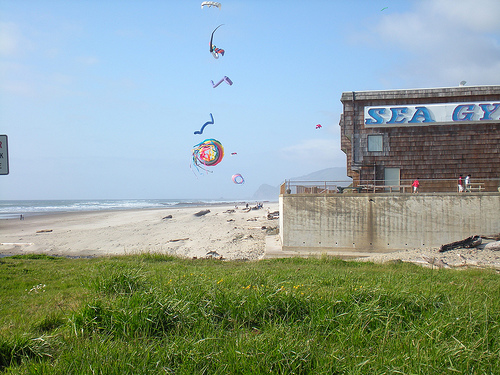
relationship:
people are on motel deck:
[407, 167, 482, 196] [283, 169, 500, 201]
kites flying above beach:
[183, 2, 331, 195] [7, 197, 283, 259]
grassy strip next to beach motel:
[1, 252, 500, 372] [259, 83, 500, 257]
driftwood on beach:
[192, 204, 217, 224] [7, 197, 283, 259]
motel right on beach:
[259, 83, 500, 257] [7, 197, 283, 259]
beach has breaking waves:
[7, 197, 283, 259] [3, 197, 168, 214]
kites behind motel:
[183, 2, 331, 195] [259, 83, 500, 257]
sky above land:
[3, 1, 494, 100] [2, 207, 497, 370]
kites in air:
[183, 2, 331, 195] [6, 5, 329, 186]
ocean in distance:
[4, 193, 265, 211] [3, 180, 337, 208]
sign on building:
[355, 99, 499, 133] [259, 83, 500, 257]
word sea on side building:
[364, 97, 443, 132] [259, 83, 500, 257]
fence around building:
[283, 169, 500, 201] [259, 83, 500, 257]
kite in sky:
[189, 135, 229, 174] [3, 1, 494, 100]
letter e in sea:
[384, 100, 411, 128] [364, 97, 443, 132]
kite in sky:
[189, 135, 229, 174] [203, 19, 234, 63]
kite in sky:
[206, 71, 235, 92] [3, 1, 494, 100]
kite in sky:
[198, 1, 225, 12] [3, 1, 494, 100]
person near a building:
[456, 170, 467, 192] [259, 83, 500, 257]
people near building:
[411, 179, 420, 194] [259, 83, 500, 257]